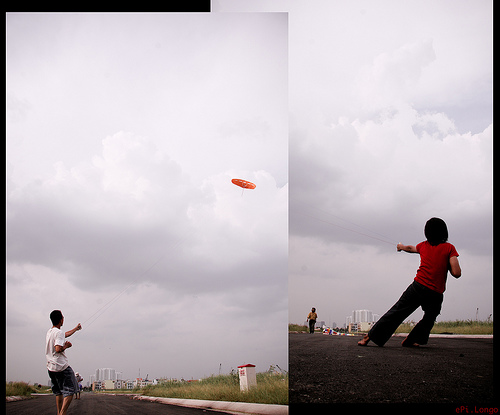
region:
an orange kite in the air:
[228, 174, 260, 195]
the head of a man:
[47, 307, 67, 328]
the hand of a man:
[75, 320, 83, 331]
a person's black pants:
[364, 277, 447, 348]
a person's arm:
[393, 239, 425, 255]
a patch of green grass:
[135, 366, 292, 405]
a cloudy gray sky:
[6, 10, 290, 385]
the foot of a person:
[355, 332, 378, 349]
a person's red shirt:
[413, 240, 460, 293]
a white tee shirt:
[44, 327, 73, 372]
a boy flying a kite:
[41, 173, 257, 413]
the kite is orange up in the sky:
[221, 175, 258, 195]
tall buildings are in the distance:
[23, 361, 204, 391]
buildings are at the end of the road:
[295, 300, 431, 345]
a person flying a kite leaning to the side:
[355, 216, 461, 351]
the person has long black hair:
[412, 215, 458, 255]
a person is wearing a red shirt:
[411, 236, 457, 288]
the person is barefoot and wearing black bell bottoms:
[355, 278, 441, 348]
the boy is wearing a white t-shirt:
[43, 323, 68, 370]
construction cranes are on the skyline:
[130, 358, 287, 390]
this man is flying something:
[11, 142, 281, 411]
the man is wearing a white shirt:
[26, 131, 278, 407]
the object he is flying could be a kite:
[194, 157, 271, 208]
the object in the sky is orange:
[212, 150, 282, 221]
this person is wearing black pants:
[360, 195, 495, 375]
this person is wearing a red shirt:
[382, 197, 467, 377]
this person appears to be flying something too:
[340, 190, 497, 385]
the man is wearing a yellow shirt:
[300, 295, 317, 340]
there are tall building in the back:
[85, 361, 171, 397]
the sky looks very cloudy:
[8, 147, 284, 317]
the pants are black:
[379, 287, 465, 333]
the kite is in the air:
[228, 171, 268, 196]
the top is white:
[41, 331, 92, 381]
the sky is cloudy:
[16, 183, 265, 293]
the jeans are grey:
[44, 368, 96, 401]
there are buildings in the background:
[86, 356, 146, 398]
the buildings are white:
[87, 363, 124, 377]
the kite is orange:
[225, 171, 265, 208]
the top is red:
[406, 241, 468, 295]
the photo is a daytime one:
[0, 15, 483, 400]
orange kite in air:
[220, 171, 265, 198]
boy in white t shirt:
[35, 292, 100, 402]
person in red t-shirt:
[371, 185, 461, 365]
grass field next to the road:
[135, 345, 312, 410]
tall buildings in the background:
[332, 300, 377, 330]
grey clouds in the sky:
[10, 15, 480, 320]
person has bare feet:
[341, 271, 443, 376]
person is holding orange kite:
[205, 148, 425, 266]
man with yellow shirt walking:
[303, 302, 320, 334]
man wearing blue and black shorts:
[31, 362, 88, 412]